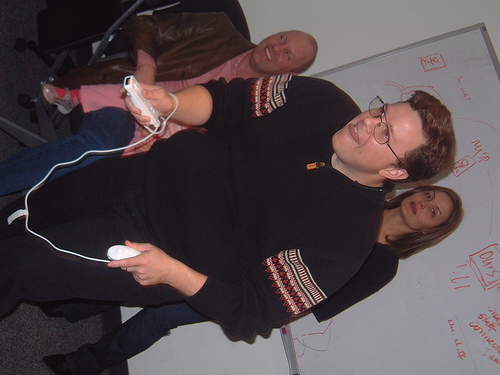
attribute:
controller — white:
[88, 74, 200, 147]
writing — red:
[412, 43, 499, 118]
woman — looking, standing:
[396, 162, 463, 236]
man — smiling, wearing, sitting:
[256, 48, 329, 74]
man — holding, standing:
[285, 87, 441, 212]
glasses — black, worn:
[363, 94, 400, 164]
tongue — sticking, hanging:
[348, 118, 367, 147]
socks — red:
[30, 72, 88, 106]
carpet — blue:
[11, 52, 41, 125]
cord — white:
[21, 166, 70, 257]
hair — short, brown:
[406, 91, 464, 193]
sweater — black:
[99, 93, 375, 310]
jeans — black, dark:
[25, 195, 138, 312]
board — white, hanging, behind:
[362, 286, 489, 355]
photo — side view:
[25, 29, 485, 366]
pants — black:
[76, 167, 154, 315]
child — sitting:
[65, 73, 268, 132]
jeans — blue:
[126, 316, 212, 361]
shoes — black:
[53, 345, 113, 375]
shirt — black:
[367, 235, 397, 309]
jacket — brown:
[152, 17, 262, 74]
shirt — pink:
[152, 58, 262, 94]